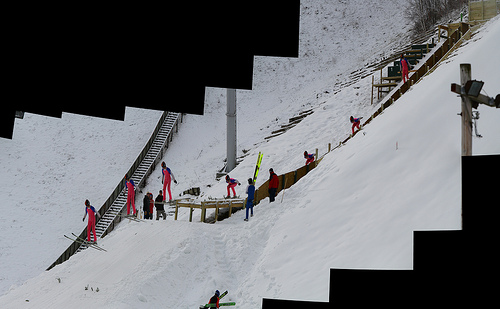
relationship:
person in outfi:
[102, 164, 156, 204] [385, 46, 439, 68]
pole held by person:
[252, 151, 260, 184] [242, 178, 256, 222]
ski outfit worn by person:
[400, 62, 410, 80] [399, 53, 413, 85]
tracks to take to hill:
[112, 129, 162, 224] [0, 0, 499, 307]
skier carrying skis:
[202, 285, 239, 307] [203, 290, 233, 305]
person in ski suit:
[82, 198, 102, 244] [82, 207, 97, 241]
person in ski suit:
[160, 161, 177, 204] [161, 167, 176, 201]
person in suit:
[123, 174, 143, 217] [122, 184, 160, 211]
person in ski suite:
[208, 155, 247, 197] [216, 162, 241, 207]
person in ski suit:
[242, 178, 256, 222] [245, 183, 256, 219]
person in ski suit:
[80, 195, 99, 242] [83, 206, 101, 243]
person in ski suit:
[161, 158, 173, 201] [161, 167, 176, 201]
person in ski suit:
[266, 168, 281, 202] [269, 171, 279, 201]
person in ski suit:
[299, 147, 316, 168] [302, 152, 316, 164]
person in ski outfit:
[399, 54, 409, 85] [399, 57, 412, 83]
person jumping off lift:
[224, 174, 241, 199] [171, 195, 251, 229]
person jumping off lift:
[160, 161, 177, 204] [171, 195, 251, 229]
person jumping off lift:
[123, 174, 143, 217] [171, 195, 251, 229]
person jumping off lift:
[82, 198, 102, 244] [171, 195, 251, 229]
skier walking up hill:
[207, 289, 219, 309] [312, 22, 492, 168]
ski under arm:
[205, 299, 235, 307] [213, 297, 219, 307]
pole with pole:
[250, 151, 258, 208] [252, 151, 260, 184]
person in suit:
[123, 174, 143, 217] [121, 180, 135, 213]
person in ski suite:
[224, 174, 241, 199] [225, 177, 239, 196]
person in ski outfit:
[399, 53, 413, 85] [399, 57, 412, 83]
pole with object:
[452, 60, 484, 151] [465, 78, 482, 95]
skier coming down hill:
[342, 111, 367, 140] [0, 0, 499, 307]